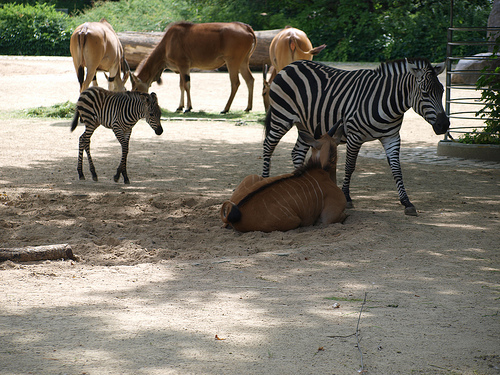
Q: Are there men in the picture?
A: No, there are no men.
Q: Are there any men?
A: No, there are no men.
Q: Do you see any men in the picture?
A: No, there are no men.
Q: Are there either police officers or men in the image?
A: No, there are no men or police officers.